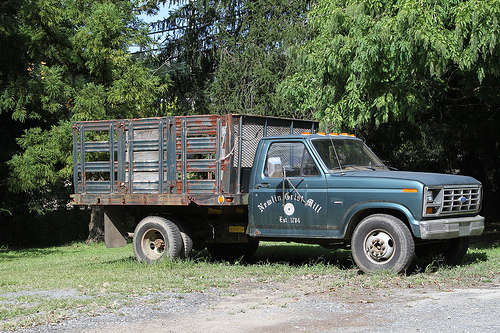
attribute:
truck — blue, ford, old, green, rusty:
[67, 110, 487, 284]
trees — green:
[2, 1, 499, 240]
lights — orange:
[302, 129, 359, 141]